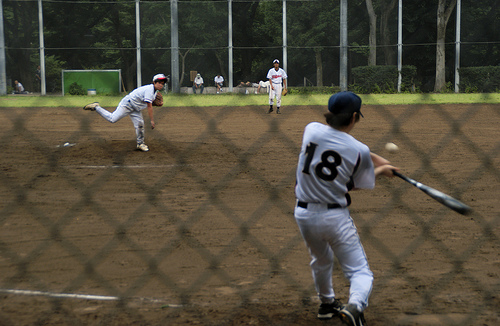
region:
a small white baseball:
[386, 140, 401, 152]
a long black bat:
[387, 164, 476, 217]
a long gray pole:
[166, 0, 186, 88]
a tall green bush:
[349, 60, 419, 94]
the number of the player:
[300, 142, 342, 189]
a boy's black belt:
[294, 201, 344, 210]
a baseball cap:
[152, 70, 172, 83]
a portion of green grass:
[2, 85, 498, 108]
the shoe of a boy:
[334, 299, 371, 324]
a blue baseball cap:
[325, 83, 369, 120]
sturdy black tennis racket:
[389, 151, 480, 233]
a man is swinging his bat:
[137, 100, 376, 315]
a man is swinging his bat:
[228, 69, 420, 323]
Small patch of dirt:
[144, 254, 164, 276]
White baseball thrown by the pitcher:
[385, 134, 400, 159]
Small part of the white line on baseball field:
[42, 285, 75, 305]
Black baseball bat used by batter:
[396, 169, 476, 216]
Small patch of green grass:
[398, 93, 411, 100]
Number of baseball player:
[303, 135, 341, 185]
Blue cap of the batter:
[332, 89, 359, 111]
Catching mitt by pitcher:
[156, 92, 166, 109]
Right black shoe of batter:
[341, 303, 366, 324]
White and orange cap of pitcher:
[153, 72, 167, 84]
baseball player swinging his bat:
[242, 63, 462, 305]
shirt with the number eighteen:
[254, 83, 405, 248]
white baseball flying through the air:
[371, 128, 409, 171]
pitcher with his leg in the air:
[43, 34, 201, 171]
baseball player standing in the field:
[240, 37, 311, 134]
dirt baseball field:
[46, 70, 474, 302]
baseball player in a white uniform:
[254, 93, 479, 290]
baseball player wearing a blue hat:
[296, 63, 396, 142]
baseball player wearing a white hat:
[82, 54, 211, 149]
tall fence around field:
[28, 9, 484, 123]